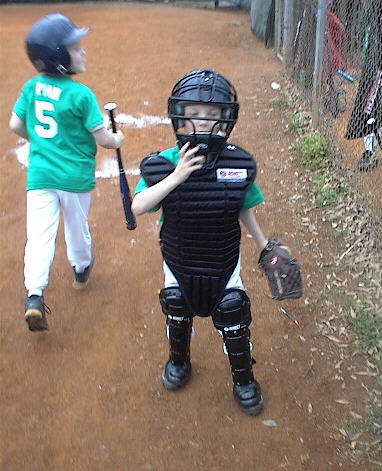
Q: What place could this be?
A: It is a field.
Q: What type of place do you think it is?
A: It is a field.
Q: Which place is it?
A: It is a field.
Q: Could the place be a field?
A: Yes, it is a field.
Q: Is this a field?
A: Yes, it is a field.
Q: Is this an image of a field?
A: Yes, it is showing a field.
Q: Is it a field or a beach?
A: It is a field.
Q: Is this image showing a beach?
A: No, the picture is showing a field.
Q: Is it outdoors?
A: Yes, it is outdoors.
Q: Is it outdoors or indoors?
A: It is outdoors.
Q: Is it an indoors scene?
A: No, it is outdoors.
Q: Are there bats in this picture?
A: Yes, there is a bat.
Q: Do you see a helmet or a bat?
A: Yes, there is a bat.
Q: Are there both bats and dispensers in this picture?
A: No, there is a bat but no dispensers.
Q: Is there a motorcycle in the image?
A: No, there are no motorcycles.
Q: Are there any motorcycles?
A: No, there are no motorcycles.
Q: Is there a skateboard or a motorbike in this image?
A: No, there are no motorcycles or skateboards.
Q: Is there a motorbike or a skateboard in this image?
A: No, there are no motorcycles or skateboards.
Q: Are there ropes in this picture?
A: No, there are no ropes.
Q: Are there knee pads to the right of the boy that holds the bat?
A: Yes, there is a knee pad to the right of the boy.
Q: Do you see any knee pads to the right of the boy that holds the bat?
A: Yes, there is a knee pad to the right of the boy.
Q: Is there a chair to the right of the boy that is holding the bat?
A: No, there is a knee pad to the right of the boy.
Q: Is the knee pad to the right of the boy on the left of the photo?
A: Yes, the knee pad is to the right of the boy.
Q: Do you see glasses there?
A: No, there are no glasses.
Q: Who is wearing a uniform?
A: The boy is wearing a uniform.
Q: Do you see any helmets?
A: Yes, there is a helmet.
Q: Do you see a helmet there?
A: Yes, there is a helmet.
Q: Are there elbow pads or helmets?
A: Yes, there is a helmet.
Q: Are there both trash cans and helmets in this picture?
A: No, there is a helmet but no trash cans.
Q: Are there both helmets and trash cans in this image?
A: No, there is a helmet but no trash cans.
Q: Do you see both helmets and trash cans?
A: No, there is a helmet but no trash cans.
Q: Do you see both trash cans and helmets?
A: No, there is a helmet but no trash cans.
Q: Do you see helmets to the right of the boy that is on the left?
A: Yes, there is a helmet to the right of the boy.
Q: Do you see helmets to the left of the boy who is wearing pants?
A: No, the helmet is to the right of the boy.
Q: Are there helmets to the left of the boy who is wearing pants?
A: No, the helmet is to the right of the boy.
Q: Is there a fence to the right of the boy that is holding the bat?
A: No, there is a helmet to the right of the boy.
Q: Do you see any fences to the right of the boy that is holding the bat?
A: No, there is a helmet to the right of the boy.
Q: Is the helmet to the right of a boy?
A: Yes, the helmet is to the right of a boy.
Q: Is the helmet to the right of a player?
A: No, the helmet is to the right of a boy.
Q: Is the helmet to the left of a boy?
A: No, the helmet is to the right of a boy.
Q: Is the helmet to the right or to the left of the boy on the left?
A: The helmet is to the right of the boy.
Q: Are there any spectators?
A: No, there are no spectators.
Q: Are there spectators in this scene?
A: No, there are no spectators.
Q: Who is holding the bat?
A: The boy is holding the bat.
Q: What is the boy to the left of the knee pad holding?
A: The boy is holding the bat.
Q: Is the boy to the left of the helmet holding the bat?
A: Yes, the boy is holding the bat.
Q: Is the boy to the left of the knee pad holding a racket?
A: No, the boy is holding the bat.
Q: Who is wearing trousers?
A: The boy is wearing trousers.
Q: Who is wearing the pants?
A: The boy is wearing trousers.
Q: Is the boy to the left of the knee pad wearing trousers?
A: Yes, the boy is wearing trousers.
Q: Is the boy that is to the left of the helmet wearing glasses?
A: No, the boy is wearing trousers.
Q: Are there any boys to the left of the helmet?
A: Yes, there is a boy to the left of the helmet.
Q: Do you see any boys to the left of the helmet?
A: Yes, there is a boy to the left of the helmet.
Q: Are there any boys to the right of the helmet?
A: No, the boy is to the left of the helmet.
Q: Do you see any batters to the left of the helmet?
A: No, there is a boy to the left of the helmet.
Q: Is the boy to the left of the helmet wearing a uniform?
A: Yes, the boy is wearing a uniform.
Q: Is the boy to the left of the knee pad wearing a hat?
A: No, the boy is wearing a uniform.